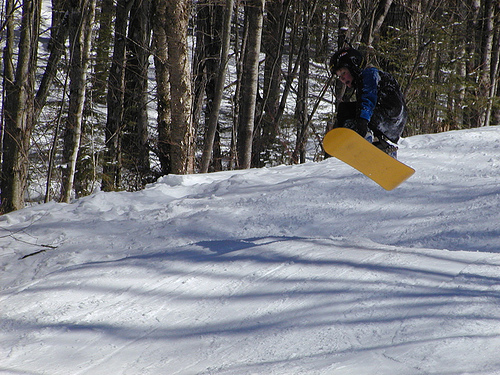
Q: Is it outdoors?
A: Yes, it is outdoors.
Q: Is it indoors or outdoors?
A: It is outdoors.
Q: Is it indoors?
A: No, it is outdoors.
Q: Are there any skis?
A: No, there are no skis.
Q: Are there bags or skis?
A: No, there are no skis or bags.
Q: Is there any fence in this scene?
A: No, there are no fences.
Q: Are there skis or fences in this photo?
A: No, there are no fences or skis.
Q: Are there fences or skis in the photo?
A: No, there are no fences or skis.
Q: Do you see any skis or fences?
A: No, there are no fences or skis.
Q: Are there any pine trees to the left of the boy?
A: Yes, there is a pine tree to the left of the boy.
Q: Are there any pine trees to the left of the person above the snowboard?
A: Yes, there is a pine tree to the left of the boy.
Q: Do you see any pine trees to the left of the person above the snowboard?
A: Yes, there is a pine tree to the left of the boy.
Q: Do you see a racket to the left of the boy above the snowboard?
A: No, there is a pine tree to the left of the boy.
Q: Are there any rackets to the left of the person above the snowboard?
A: No, there is a pine tree to the left of the boy.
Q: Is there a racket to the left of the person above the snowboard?
A: No, there is a pine tree to the left of the boy.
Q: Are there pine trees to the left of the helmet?
A: Yes, there is a pine tree to the left of the helmet.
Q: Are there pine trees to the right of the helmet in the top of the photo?
A: No, the pine tree is to the left of the helmet.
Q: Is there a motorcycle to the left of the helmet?
A: No, there is a pine tree to the left of the helmet.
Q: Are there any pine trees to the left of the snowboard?
A: Yes, there is a pine tree to the left of the snowboard.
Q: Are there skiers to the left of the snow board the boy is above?
A: No, there is a pine tree to the left of the snowboard.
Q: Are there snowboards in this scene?
A: Yes, there is a snowboard.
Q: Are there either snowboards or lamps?
A: Yes, there is a snowboard.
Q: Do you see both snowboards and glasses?
A: No, there is a snowboard but no glasses.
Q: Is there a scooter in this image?
A: No, there are no scooters.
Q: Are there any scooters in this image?
A: No, there are no scooters.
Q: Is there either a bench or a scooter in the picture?
A: No, there are no scooters or benches.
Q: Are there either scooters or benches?
A: No, there are no scooters or benches.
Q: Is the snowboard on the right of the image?
A: Yes, the snowboard is on the right of the image.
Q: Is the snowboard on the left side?
A: No, the snowboard is on the right of the image.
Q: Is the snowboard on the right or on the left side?
A: The snowboard is on the right of the image.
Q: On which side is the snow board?
A: The snow board is on the right of the image.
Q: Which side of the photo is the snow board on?
A: The snow board is on the right of the image.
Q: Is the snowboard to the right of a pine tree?
A: Yes, the snowboard is to the right of a pine tree.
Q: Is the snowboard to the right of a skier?
A: No, the snowboard is to the right of a pine tree.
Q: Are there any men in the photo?
A: No, there are no men.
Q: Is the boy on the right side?
A: Yes, the boy is on the right of the image.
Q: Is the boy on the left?
A: No, the boy is on the right of the image.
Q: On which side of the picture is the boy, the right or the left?
A: The boy is on the right of the image.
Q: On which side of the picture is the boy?
A: The boy is on the right of the image.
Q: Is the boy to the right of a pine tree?
A: Yes, the boy is to the right of a pine tree.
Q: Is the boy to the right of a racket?
A: No, the boy is to the right of a pine tree.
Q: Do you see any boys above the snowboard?
A: Yes, there is a boy above the snowboard.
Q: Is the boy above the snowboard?
A: Yes, the boy is above the snowboard.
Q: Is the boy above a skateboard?
A: No, the boy is above the snowboard.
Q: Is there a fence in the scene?
A: No, there are no fences.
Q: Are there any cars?
A: No, there are no cars.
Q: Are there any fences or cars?
A: No, there are no cars or fences.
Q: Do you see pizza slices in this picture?
A: No, there are no pizza slices.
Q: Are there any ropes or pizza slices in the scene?
A: No, there are no pizza slices or ropes.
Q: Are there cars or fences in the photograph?
A: No, there are no cars or fences.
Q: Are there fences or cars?
A: No, there are no cars or fences.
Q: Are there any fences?
A: No, there are no fences.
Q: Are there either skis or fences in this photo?
A: No, there are no fences or skis.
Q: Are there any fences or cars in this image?
A: No, there are no fences or cars.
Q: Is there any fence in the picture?
A: No, there are no fences.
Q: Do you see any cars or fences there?
A: No, there are no fences or cars.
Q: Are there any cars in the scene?
A: No, there are no cars.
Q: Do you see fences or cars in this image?
A: No, there are no cars or fences.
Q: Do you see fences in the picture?
A: No, there are no fences.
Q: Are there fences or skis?
A: No, there are no fences or skis.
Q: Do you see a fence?
A: No, there are no fences.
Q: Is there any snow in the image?
A: Yes, there is snow.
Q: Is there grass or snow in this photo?
A: Yes, there is snow.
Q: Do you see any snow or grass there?
A: Yes, there is snow.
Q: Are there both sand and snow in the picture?
A: No, there is snow but no sand.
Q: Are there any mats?
A: No, there are no mats.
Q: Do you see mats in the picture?
A: No, there are no mats.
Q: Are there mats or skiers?
A: No, there are no mats or skiers.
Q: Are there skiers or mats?
A: No, there are no mats or skiers.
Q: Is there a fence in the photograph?
A: No, there are no fences.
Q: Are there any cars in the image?
A: No, there are no cars.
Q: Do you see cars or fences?
A: No, there are no cars or fences.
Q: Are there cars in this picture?
A: No, there are no cars.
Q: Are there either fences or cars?
A: No, there are no cars or fences.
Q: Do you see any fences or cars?
A: No, there are no cars or fences.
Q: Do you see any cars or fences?
A: No, there are no cars or fences.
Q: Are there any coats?
A: Yes, there is a coat.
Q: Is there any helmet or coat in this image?
A: Yes, there is a coat.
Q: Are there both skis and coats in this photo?
A: No, there is a coat but no skis.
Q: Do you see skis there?
A: No, there are no skis.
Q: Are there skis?
A: No, there are no skis.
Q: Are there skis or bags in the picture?
A: No, there are no skis or bags.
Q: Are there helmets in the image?
A: Yes, there is a helmet.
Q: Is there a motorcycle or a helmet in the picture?
A: Yes, there is a helmet.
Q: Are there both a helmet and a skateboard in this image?
A: No, there is a helmet but no skateboards.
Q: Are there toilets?
A: No, there are no toilets.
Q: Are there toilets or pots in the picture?
A: No, there are no toilets or pots.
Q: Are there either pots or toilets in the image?
A: No, there are no toilets or pots.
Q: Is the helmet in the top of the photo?
A: Yes, the helmet is in the top of the image.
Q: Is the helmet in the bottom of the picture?
A: No, the helmet is in the top of the image.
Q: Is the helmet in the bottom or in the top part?
A: The helmet is in the top of the image.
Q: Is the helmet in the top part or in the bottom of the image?
A: The helmet is in the top of the image.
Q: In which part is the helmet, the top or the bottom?
A: The helmet is in the top of the image.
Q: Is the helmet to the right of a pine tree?
A: Yes, the helmet is to the right of a pine tree.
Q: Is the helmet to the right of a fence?
A: No, the helmet is to the right of a pine tree.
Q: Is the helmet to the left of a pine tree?
A: No, the helmet is to the right of a pine tree.